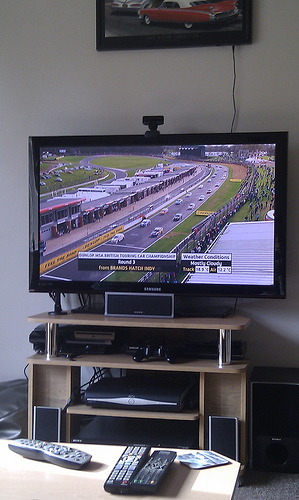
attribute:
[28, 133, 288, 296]
frame — black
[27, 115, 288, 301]
television — flat screen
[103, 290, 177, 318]
speaker — grey, sony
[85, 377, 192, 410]
box — cable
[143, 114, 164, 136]
camera — small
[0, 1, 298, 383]
wall — white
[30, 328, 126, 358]
system — black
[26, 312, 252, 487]
center — wood, wood color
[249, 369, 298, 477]
speaker — black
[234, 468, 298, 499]
carpet — grey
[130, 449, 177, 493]
control — black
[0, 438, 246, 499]
table — tan, wood color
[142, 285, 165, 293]
logo — white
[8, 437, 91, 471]
remote — black